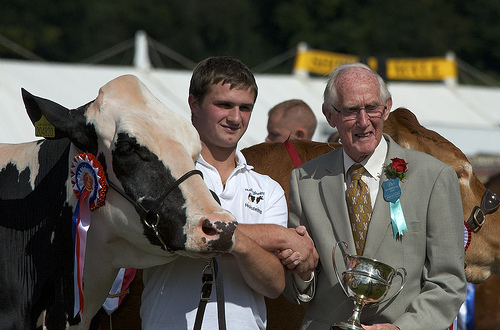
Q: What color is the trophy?
A: Silver.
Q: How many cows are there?
A: One.